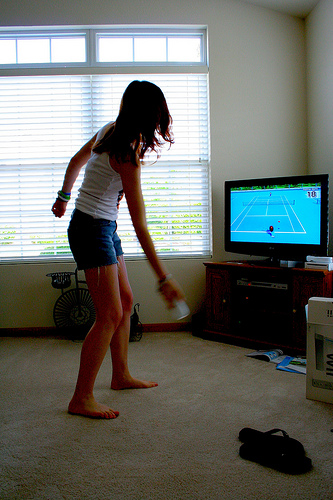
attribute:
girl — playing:
[43, 71, 192, 426]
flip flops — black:
[233, 419, 314, 480]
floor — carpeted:
[1, 324, 331, 500]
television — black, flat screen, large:
[220, 170, 332, 264]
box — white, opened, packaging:
[299, 290, 332, 407]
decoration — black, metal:
[43, 265, 106, 348]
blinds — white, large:
[2, 73, 219, 265]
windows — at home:
[1, 24, 220, 270]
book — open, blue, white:
[246, 342, 286, 372]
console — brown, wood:
[189, 253, 332, 368]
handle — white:
[159, 282, 195, 322]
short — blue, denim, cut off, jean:
[62, 210, 130, 274]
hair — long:
[90, 80, 178, 171]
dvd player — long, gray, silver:
[233, 271, 286, 292]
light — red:
[245, 280, 252, 288]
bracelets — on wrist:
[57, 187, 71, 201]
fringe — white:
[94, 265, 102, 284]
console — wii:
[300, 255, 332, 271]